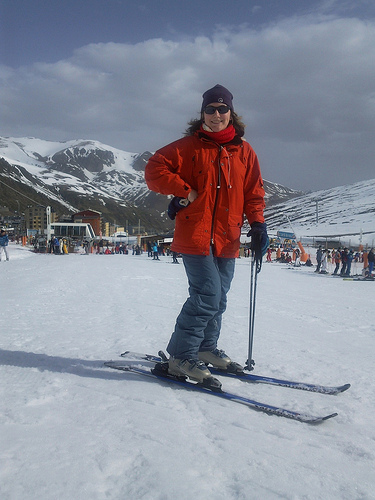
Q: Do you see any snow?
A: Yes, there is snow.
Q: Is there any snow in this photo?
A: Yes, there is snow.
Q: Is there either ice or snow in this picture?
A: Yes, there is snow.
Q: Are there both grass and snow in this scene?
A: No, there is snow but no grass.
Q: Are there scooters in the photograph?
A: No, there are no scooters.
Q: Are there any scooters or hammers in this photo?
A: No, there are no scooters or hammers.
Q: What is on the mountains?
A: The snow is on the mountains.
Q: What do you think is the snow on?
A: The snow is on the mountains.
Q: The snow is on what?
A: The snow is on the mountains.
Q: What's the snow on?
A: The snow is on the mountains.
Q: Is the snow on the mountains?
A: Yes, the snow is on the mountains.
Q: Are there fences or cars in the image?
A: No, there are no fences or cars.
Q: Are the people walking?
A: Yes, the people are walking.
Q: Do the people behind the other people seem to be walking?
A: Yes, the people are walking.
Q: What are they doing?
A: The people are walking.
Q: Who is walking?
A: The people are walking.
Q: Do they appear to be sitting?
A: No, the people are walking.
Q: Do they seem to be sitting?
A: No, the people are walking.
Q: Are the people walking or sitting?
A: The people are walking.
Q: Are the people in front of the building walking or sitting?
A: The people are walking.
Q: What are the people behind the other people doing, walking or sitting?
A: The people are walking.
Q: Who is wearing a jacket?
A: The people are wearing a jacket.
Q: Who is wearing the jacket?
A: The people are wearing a jacket.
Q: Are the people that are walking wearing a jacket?
A: Yes, the people are wearing a jacket.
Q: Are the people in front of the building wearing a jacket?
A: Yes, the people are wearing a jacket.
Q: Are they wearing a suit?
A: No, the people are wearing a jacket.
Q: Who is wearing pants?
A: The people are wearing pants.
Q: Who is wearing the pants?
A: The people are wearing pants.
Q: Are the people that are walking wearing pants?
A: Yes, the people are wearing pants.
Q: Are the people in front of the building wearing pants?
A: Yes, the people are wearing pants.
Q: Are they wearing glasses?
A: No, the people are wearing pants.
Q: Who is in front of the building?
A: The people are in front of the building.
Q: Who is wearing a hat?
A: The people are wearing a hat.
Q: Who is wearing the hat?
A: The people are wearing a hat.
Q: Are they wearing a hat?
A: Yes, the people are wearing a hat.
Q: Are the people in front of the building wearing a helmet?
A: No, the people are wearing a hat.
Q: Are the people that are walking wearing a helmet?
A: No, the people are wearing a hat.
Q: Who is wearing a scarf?
A: The people are wearing a scarf.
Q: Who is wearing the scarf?
A: The people are wearing a scarf.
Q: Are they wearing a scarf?
A: Yes, the people are wearing a scarf.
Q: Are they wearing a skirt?
A: No, the people are wearing a scarf.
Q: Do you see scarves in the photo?
A: Yes, there is a scarf.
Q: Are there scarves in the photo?
A: Yes, there is a scarf.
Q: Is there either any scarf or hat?
A: Yes, there is a scarf.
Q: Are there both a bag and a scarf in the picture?
A: No, there is a scarf but no bags.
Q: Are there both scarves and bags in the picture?
A: No, there is a scarf but no bags.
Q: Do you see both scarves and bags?
A: No, there is a scarf but no bags.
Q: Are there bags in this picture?
A: No, there are no bags.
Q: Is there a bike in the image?
A: No, there are no bikes.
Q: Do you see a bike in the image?
A: No, there are no bikes.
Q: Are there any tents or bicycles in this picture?
A: No, there are no bicycles or tents.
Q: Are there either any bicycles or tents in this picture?
A: No, there are no bicycles or tents.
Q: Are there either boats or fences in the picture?
A: No, there are no fences or boats.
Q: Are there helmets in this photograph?
A: No, there are no helmets.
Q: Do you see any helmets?
A: No, there are no helmets.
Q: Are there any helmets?
A: No, there are no helmets.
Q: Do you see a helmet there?
A: No, there are no helmets.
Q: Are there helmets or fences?
A: No, there are no helmets or fences.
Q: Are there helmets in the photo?
A: No, there are no helmets.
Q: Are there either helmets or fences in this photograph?
A: No, there are no helmets or fences.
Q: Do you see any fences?
A: No, there are no fences.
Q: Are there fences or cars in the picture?
A: No, there are no fences or cars.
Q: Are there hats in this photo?
A: Yes, there is a hat.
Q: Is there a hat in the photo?
A: Yes, there is a hat.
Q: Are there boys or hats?
A: Yes, there is a hat.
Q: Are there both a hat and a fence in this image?
A: No, there is a hat but no fences.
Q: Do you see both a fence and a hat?
A: No, there is a hat but no fences.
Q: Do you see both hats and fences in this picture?
A: No, there is a hat but no fences.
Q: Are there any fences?
A: No, there are no fences.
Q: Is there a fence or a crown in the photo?
A: No, there are no fences or crowns.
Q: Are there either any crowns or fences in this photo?
A: No, there are no fences or crowns.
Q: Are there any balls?
A: No, there are no balls.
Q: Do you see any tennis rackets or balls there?
A: No, there are no balls or tennis rackets.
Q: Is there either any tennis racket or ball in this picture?
A: No, there are no balls or rackets.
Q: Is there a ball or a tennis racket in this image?
A: No, there are no balls or rackets.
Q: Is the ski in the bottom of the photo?
A: Yes, the ski is in the bottom of the image.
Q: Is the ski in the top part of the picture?
A: No, the ski is in the bottom of the image.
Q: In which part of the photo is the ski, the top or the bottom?
A: The ski is in the bottom of the image.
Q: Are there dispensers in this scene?
A: No, there are no dispensers.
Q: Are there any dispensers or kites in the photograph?
A: No, there are no dispensers or kites.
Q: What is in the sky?
A: The clouds are in the sky.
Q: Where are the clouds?
A: The clouds are in the sky.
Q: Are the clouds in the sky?
A: Yes, the clouds are in the sky.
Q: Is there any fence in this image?
A: No, there are no fences.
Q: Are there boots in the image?
A: Yes, there are boots.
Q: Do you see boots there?
A: Yes, there are boots.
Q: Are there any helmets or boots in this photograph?
A: Yes, there are boots.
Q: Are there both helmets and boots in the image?
A: No, there are boots but no helmets.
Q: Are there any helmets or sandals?
A: No, there are no helmets or sandals.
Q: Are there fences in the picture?
A: No, there are no fences.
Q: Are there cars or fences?
A: No, there are no fences or cars.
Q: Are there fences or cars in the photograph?
A: No, there are no fences or cars.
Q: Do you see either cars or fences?
A: No, there are no fences or cars.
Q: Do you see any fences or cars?
A: No, there are no fences or cars.